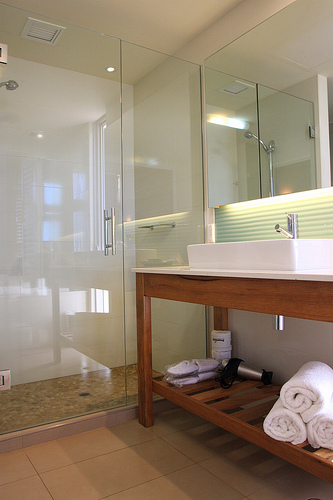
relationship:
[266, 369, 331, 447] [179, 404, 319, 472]
towels on shelf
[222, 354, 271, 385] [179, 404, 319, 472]
blow dryer on shelf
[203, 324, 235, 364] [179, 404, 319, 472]
toilet paper on shelf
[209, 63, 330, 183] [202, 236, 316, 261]
mirror above sink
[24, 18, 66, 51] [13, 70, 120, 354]
vent over shower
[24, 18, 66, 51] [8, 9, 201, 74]
vent on ceiling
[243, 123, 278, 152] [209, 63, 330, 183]
shower head in mirror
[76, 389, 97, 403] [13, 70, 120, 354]
drain in shower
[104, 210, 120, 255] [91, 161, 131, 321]
handle on door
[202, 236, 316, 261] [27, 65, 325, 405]
sink in bathroom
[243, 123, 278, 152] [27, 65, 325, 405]
shower head in bathroom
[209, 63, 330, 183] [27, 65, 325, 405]
mirror in bathroom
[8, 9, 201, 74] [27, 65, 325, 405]
ceiling in bathroom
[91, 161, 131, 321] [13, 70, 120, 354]
door on shower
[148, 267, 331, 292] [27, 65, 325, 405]
table in bathroom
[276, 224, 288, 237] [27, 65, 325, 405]
tap in bathroom